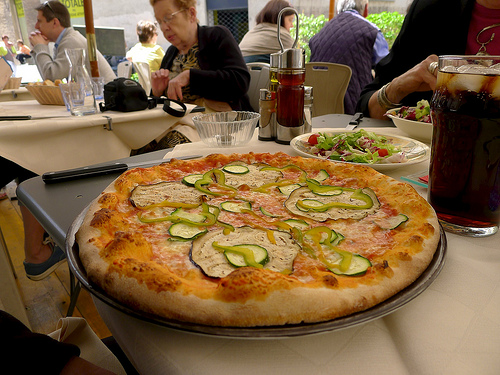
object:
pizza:
[74, 155, 442, 327]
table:
[19, 152, 497, 369]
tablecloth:
[96, 142, 500, 372]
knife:
[39, 152, 202, 187]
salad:
[306, 134, 400, 159]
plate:
[289, 127, 431, 166]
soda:
[430, 55, 498, 235]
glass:
[433, 57, 498, 233]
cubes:
[436, 62, 499, 98]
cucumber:
[229, 242, 268, 268]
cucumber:
[169, 222, 209, 242]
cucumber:
[226, 198, 251, 216]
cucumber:
[330, 252, 370, 278]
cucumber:
[226, 164, 252, 177]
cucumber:
[186, 171, 214, 190]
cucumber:
[303, 199, 326, 214]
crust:
[81, 156, 437, 325]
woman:
[146, 2, 252, 115]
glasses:
[152, 11, 182, 25]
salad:
[397, 97, 432, 123]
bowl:
[384, 103, 436, 144]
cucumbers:
[173, 166, 405, 279]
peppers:
[143, 169, 372, 276]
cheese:
[102, 153, 433, 291]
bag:
[97, 77, 187, 119]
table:
[2, 93, 197, 164]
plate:
[64, 152, 448, 339]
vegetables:
[167, 164, 407, 278]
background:
[3, 3, 499, 114]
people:
[234, 4, 386, 120]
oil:
[268, 51, 282, 130]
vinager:
[280, 49, 304, 135]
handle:
[44, 165, 128, 188]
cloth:
[0, 101, 194, 176]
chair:
[299, 61, 352, 117]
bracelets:
[373, 82, 404, 111]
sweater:
[157, 22, 249, 111]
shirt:
[34, 25, 116, 96]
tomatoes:
[307, 134, 392, 163]